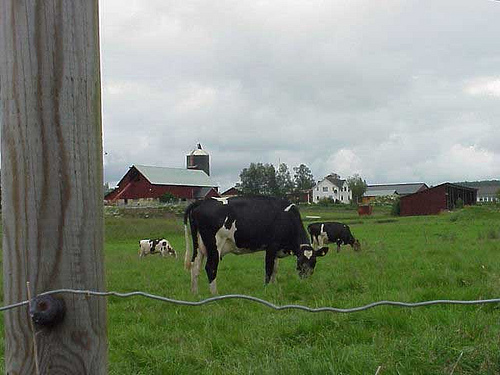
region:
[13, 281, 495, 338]
Silver colored wire on a wooden post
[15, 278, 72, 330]
Black knob on a wooden post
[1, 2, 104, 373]
Grayish wooden post holding a wire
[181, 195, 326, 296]
A cow is eating grass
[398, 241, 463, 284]
Green grass on the ground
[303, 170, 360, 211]
White house in the distance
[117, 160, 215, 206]
Red building in the distance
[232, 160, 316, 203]
Green trees in the distance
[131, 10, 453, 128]
A dark cloudy sky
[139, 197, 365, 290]
Three cows are feeding on grass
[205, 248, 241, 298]
leg of a cow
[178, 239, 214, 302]
leg of a cow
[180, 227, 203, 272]
tail of a cow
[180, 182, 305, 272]
body of a cow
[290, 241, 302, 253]
ear of a cow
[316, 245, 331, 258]
ear of a cow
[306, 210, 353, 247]
body of a cow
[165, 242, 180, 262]
head of a cow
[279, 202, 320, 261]
neck of a cow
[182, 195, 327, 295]
Cow looking at the grass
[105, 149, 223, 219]
Barn distant from the cow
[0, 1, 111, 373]
Wooden post on the ground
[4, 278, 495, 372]
Wired fence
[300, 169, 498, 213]
Several buildings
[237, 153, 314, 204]
Row of green trees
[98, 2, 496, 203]
Cloudy sky outside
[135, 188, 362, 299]
Couple of cows wandering in the farmland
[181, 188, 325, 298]
Cow with a black face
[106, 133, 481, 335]
cows in a pasture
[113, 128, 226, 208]
a red barn and silo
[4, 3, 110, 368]
a wooden fence post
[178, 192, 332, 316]
a cow eating grass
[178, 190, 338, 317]
a black and white cow eating grass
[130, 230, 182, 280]
a cow eating grass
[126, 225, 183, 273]
a black and white cow eating grass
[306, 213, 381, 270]
a black and white cow eating grass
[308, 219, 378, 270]
a cow eating grass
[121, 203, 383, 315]
several cows grazing on grass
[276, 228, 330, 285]
cow with its head down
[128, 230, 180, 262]
white and black cow grazing grass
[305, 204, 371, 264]
cow with its head in the grass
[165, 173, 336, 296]
cow grazing grass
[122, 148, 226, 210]
red barn in the field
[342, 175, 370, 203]
tree in the field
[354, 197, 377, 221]
red bin in the field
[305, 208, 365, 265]
cow with its head down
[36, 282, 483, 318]
wire on the fence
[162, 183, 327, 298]
cow with its head down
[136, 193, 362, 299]
Three black and white cow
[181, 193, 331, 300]
Black and white cow has white tail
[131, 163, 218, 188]
White roof in the background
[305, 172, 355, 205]
Large white house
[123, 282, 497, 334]
the wire is metal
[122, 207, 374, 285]
the cows are grazing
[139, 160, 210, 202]
the roof is tin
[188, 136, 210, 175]
the silo is by the barn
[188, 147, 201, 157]
tin roof is on silo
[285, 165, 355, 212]
trees around the house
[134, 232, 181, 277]
the white cow is in pasture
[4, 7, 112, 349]
the post is wooden